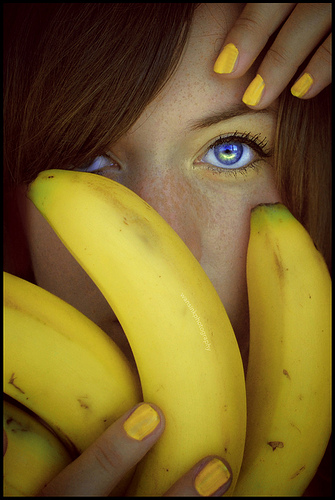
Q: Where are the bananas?
A: In front of the woman's face.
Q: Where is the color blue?
A: In the girl's eyes.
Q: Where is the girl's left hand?
A: On her head.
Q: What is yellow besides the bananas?
A: The fingernails.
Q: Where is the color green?
A: On the tip of the banana on the right.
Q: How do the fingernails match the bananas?
A: Color.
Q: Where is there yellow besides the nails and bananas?
A: Eyeshadow.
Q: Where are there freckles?
A: Girls face.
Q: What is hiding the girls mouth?
A: Banana's.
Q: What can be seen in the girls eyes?
A: Reflection of light.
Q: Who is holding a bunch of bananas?
A: Red hair girl.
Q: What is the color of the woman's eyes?
A: Blue.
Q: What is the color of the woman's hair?
A: Brown.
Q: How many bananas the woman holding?
A: Four.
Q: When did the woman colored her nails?
A: Earlier.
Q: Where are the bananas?
A: On the woman's face.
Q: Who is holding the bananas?
A: A woman.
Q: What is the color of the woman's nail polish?
A: Yellow.